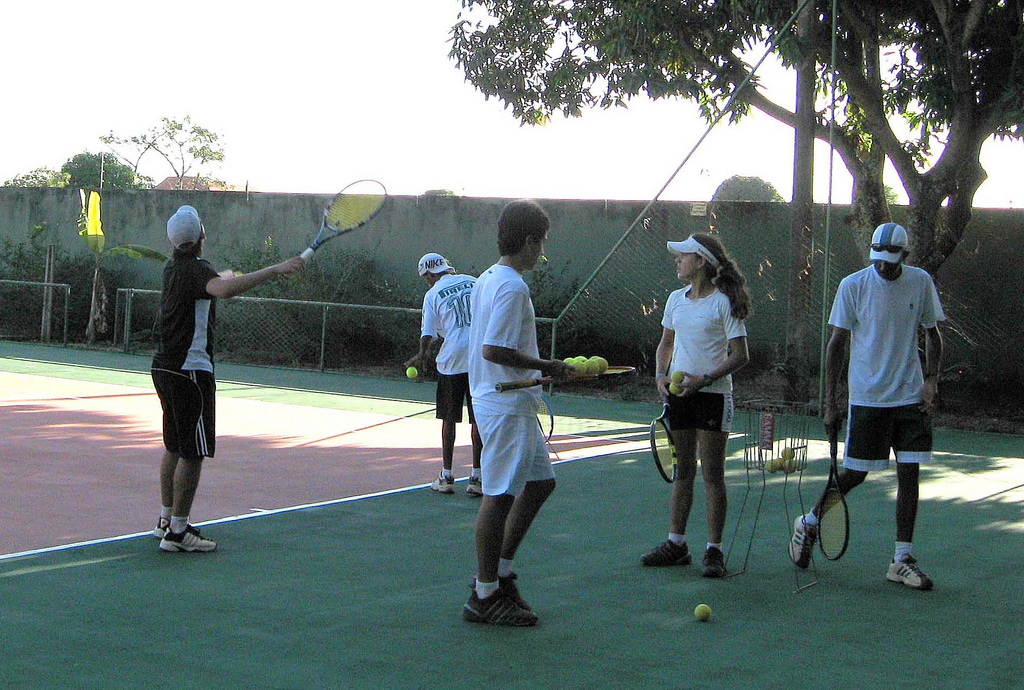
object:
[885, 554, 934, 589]
shoe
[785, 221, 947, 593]
person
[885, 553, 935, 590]
foot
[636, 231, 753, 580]
girl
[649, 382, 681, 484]
tennis racket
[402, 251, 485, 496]
tennis player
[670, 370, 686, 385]
tennis ball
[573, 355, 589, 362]
tennis ball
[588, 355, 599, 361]
tennis ball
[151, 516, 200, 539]
shoe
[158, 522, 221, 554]
foot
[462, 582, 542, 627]
foot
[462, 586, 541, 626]
shoe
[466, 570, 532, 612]
shoe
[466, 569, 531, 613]
foot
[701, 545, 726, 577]
shoe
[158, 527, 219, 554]
shoe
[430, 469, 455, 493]
shoe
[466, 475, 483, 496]
shoe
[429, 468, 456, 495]
foot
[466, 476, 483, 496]
foot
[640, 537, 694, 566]
shoe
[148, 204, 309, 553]
boy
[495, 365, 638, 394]
racket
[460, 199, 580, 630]
boy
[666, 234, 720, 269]
visor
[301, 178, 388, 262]
racket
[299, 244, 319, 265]
handle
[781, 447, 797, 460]
balls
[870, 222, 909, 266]
cap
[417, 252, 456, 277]
cap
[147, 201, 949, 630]
people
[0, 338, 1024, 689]
court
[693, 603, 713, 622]
ball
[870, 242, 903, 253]
sunglasses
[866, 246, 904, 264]
brim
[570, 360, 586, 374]
balls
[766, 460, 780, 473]
balls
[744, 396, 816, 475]
basket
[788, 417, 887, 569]
leg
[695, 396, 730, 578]
leg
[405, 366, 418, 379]
ball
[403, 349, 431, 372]
hand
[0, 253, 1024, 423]
greenery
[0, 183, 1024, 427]
wall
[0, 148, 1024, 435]
fence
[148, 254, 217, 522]
body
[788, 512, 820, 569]
shoe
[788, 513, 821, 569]
foot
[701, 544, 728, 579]
foot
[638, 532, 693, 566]
foot